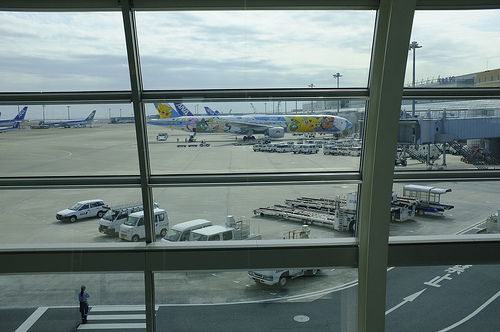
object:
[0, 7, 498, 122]
sky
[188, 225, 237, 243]
car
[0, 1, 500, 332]
window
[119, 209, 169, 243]
car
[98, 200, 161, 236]
car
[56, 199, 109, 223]
car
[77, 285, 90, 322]
person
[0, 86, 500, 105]
frames